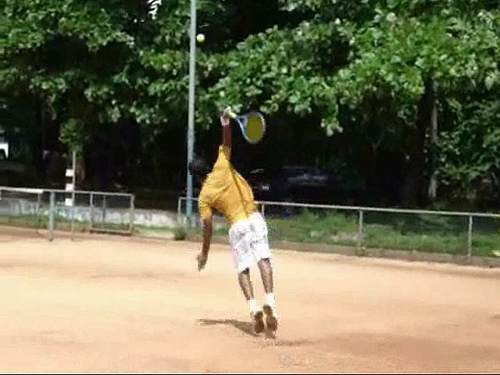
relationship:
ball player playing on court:
[189, 106, 281, 338] [325, 317, 444, 361]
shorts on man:
[218, 216, 327, 284] [154, 114, 285, 338]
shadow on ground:
[195, 316, 255, 332] [0, 230, 498, 372]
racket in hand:
[225, 113, 267, 150] [212, 107, 232, 133]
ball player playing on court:
[189, 106, 281, 338] [0, 186, 498, 373]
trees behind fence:
[276, 37, 479, 192] [278, 187, 485, 225]